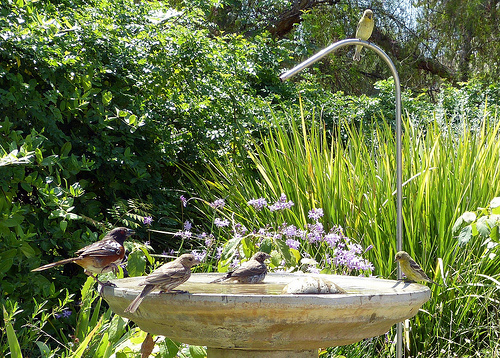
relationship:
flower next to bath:
[177, 192, 376, 277] [102, 271, 414, 292]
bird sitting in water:
[208, 252, 273, 284] [232, 283, 266, 290]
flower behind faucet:
[177, 192, 376, 277] [32, 172, 474, 357]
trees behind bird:
[2, 2, 482, 228] [345, 5, 384, 60]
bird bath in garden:
[91, 259, 431, 354] [80, 72, 498, 329]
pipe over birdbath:
[277, 34, 407, 356] [99, 266, 435, 356]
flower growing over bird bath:
[177, 192, 376, 277] [91, 259, 431, 354]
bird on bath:
[30, 227, 136, 288] [98, 35, 430, 350]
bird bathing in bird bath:
[220, 255, 271, 282] [109, 269, 426, 352]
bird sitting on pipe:
[355, 6, 425, 63] [315, 39, 466, 253]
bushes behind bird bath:
[206, 95, 499, 358] [111, 272, 407, 344]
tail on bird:
[121, 284, 151, 316] [124, 249, 204, 317]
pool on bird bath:
[91, 268, 431, 357] [31, 225, 430, 312]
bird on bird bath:
[27, 225, 137, 292] [109, 269, 426, 352]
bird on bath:
[395, 251, 432, 283] [100, 272, 431, 353]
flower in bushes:
[331, 245, 368, 272] [206, 114, 458, 246]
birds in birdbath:
[27, 217, 200, 314] [99, 266, 435, 356]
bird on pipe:
[123, 248, 205, 324] [393, 110, 405, 235]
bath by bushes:
[97, 35, 430, 357] [206, 95, 499, 358]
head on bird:
[104, 217, 138, 243] [24, 219, 145, 272]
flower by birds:
[177, 192, 376, 277] [127, 233, 289, 308]